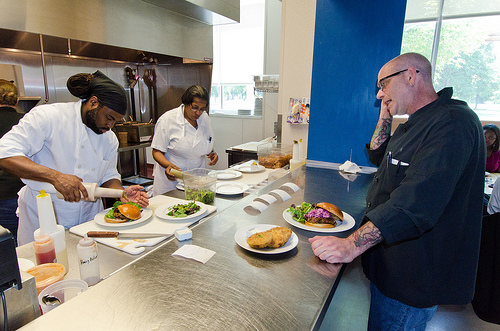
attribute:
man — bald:
[342, 29, 499, 329]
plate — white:
[290, 219, 308, 230]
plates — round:
[213, 166, 246, 203]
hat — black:
[81, 76, 122, 99]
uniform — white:
[156, 115, 215, 164]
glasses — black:
[371, 70, 392, 87]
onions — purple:
[303, 207, 330, 218]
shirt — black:
[411, 117, 458, 152]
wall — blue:
[316, 16, 361, 119]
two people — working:
[7, 55, 227, 192]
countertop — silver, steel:
[229, 209, 251, 224]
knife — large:
[88, 228, 169, 239]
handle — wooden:
[84, 230, 121, 240]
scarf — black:
[74, 64, 107, 93]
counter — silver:
[305, 169, 321, 186]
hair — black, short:
[184, 93, 194, 101]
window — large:
[402, 9, 499, 58]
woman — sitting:
[482, 118, 500, 169]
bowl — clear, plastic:
[193, 179, 212, 192]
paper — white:
[165, 242, 219, 270]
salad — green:
[286, 200, 308, 223]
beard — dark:
[85, 115, 95, 128]